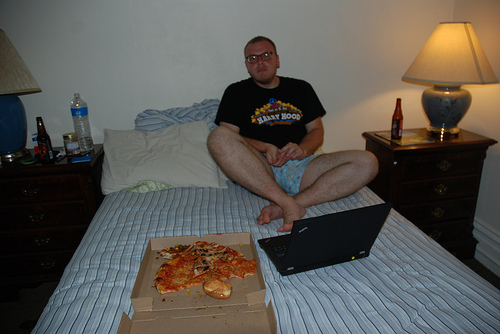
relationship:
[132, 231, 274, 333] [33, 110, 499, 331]
box on bed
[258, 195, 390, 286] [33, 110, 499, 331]
laptop on bed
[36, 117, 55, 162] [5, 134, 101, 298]
bottle on stand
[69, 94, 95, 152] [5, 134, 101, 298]
water bottle on stand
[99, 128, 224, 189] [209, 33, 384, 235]
pillow near man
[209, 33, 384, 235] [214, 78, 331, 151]
man wears shirt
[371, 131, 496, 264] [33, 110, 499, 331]
nightstand near bed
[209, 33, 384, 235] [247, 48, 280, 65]
man wears glasses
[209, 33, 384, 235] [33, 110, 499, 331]
man in bed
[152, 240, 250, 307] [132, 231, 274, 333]
pizza in box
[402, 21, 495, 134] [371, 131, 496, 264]
lamp on nightstand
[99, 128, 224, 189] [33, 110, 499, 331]
pillow on bed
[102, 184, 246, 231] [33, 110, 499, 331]
sheet on bed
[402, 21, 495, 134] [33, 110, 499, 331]
lamp by bed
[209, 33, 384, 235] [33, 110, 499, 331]
man on bed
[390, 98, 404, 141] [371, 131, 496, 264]
bottle on nightstand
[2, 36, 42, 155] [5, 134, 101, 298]
lamp on stand